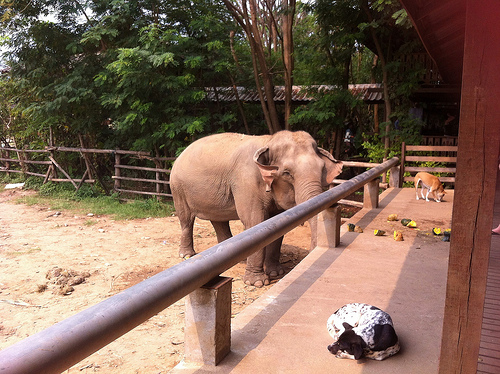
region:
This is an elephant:
[153, 98, 380, 331]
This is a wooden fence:
[24, 124, 361, 219]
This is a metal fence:
[4, 146, 406, 369]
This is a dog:
[321, 289, 401, 365]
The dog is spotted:
[317, 290, 410, 368]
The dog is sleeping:
[324, 300, 404, 362]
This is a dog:
[405, 163, 460, 211]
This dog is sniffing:
[415, 160, 453, 205]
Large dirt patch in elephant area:
[5, 176, 302, 371]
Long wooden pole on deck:
[420, 1, 498, 370]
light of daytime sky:
[8, 1, 312, 67]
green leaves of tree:
[109, 33, 211, 152]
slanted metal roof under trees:
[214, 83, 388, 101]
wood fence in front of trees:
[3, 139, 375, 214]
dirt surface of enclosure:
[0, 203, 297, 368]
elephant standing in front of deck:
[167, 129, 343, 285]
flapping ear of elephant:
[256, 145, 281, 191]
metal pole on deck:
[46, 155, 397, 372]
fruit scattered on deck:
[343, 211, 448, 243]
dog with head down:
[408, 170, 446, 202]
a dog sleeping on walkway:
[292, 284, 412, 371]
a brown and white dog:
[397, 158, 452, 214]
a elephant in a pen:
[102, 127, 355, 322]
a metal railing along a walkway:
[192, 142, 413, 314]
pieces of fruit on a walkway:
[363, 198, 446, 260]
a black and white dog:
[315, 284, 410, 365]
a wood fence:
[4, 141, 154, 198]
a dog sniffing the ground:
[413, 167, 449, 224]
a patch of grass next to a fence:
[37, 188, 154, 220]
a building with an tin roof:
[217, 78, 391, 115]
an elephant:
[139, 120, 343, 285]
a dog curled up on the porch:
[315, 292, 408, 372]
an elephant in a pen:
[6, 122, 378, 372]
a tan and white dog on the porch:
[408, 167, 445, 208]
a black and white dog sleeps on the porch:
[316, 297, 407, 366]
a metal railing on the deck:
[24, 147, 403, 367]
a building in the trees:
[165, 77, 400, 157]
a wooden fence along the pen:
[8, 130, 407, 209]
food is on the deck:
[346, 195, 452, 250]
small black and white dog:
[321, 300, 403, 360]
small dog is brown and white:
[411, 169, 446, 203]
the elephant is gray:
[170, 129, 342, 284]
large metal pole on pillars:
[1, 155, 401, 372]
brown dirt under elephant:
[0, 198, 346, 372]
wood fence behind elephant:
[0, 136, 458, 203]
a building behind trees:
[188, 78, 461, 185]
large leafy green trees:
[1, 0, 458, 188]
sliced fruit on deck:
[345, 205, 453, 250]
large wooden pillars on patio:
[433, 0, 498, 372]